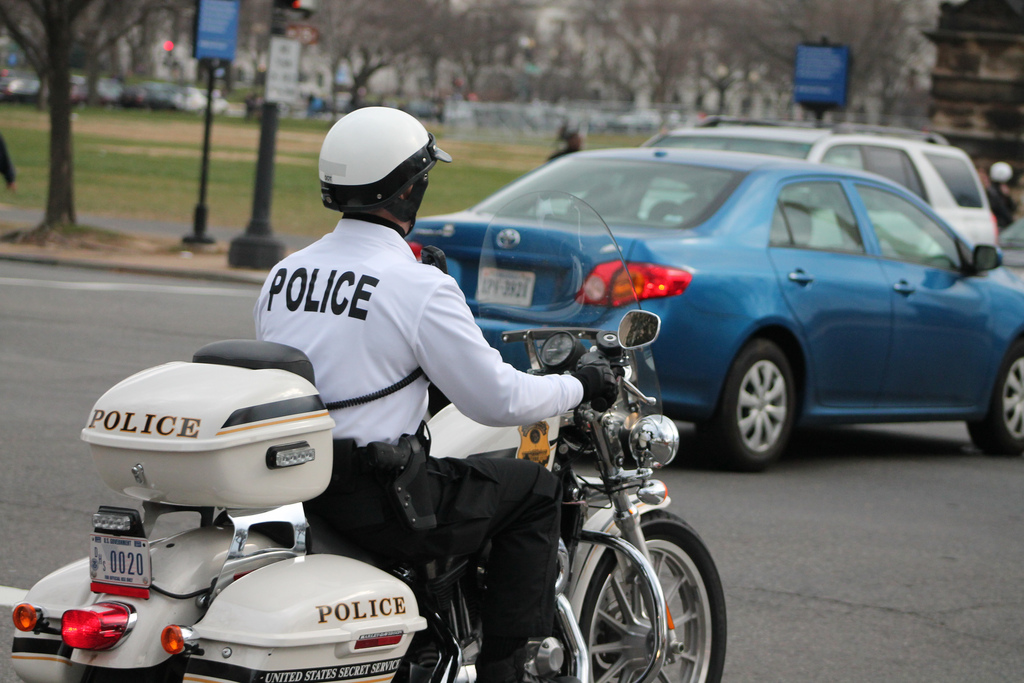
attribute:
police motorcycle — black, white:
[7, 182, 731, 679]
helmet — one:
[307, 95, 457, 208]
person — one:
[275, 83, 598, 632]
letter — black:
[328, 267, 355, 317]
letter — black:
[267, 263, 289, 309]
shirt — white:
[254, 217, 577, 440]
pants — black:
[308, 442, 577, 646]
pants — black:
[310, 442, 565, 680]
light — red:
[583, 258, 689, 311]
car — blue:
[414, 152, 1020, 470]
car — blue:
[398, 139, 962, 466]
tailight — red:
[580, 251, 689, 304]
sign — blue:
[197, 5, 237, 60]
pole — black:
[185, 53, 222, 241]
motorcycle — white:
[6, 298, 750, 677]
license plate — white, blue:
[77, 526, 160, 604]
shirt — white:
[220, 214, 577, 530]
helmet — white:
[306, 96, 430, 205]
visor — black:
[402, 124, 482, 189]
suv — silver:
[633, 89, 1022, 345]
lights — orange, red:
[41, 582, 141, 660]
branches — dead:
[37, 13, 107, 94]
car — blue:
[345, 50, 1022, 515]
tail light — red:
[577, 251, 694, 331]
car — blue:
[414, 91, 1007, 480]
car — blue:
[402, 74, 1012, 502]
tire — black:
[723, 337, 823, 459]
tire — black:
[706, 324, 827, 497]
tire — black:
[695, 314, 806, 485]